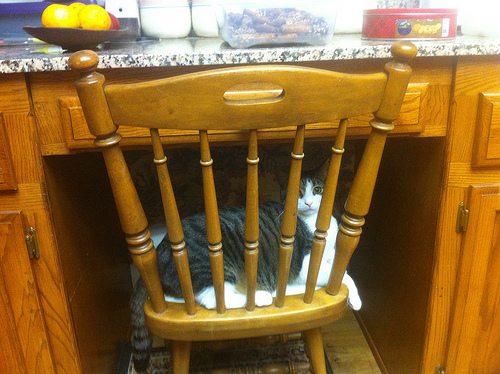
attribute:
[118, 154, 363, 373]
cat — gray, white, tiger, grey, laying, seated, looking, hiding, striped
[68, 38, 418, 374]
chair — brown, wood, pushed up, wooden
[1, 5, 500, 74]
counter — marbled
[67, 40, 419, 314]
dowels — wooden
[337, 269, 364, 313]
white front leg — hanging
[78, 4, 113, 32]
lemon — yellow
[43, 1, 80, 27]
lemon — yellow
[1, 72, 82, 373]
cupboard — wood, light colored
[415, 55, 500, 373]
cupboard — wood, light colored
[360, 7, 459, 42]
tin — red, round, metal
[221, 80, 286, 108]
cutout — oval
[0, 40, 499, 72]
countertop edge — marbled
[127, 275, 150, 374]
tail — striped, hanging down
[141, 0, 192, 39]
jar — white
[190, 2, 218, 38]
jar — white